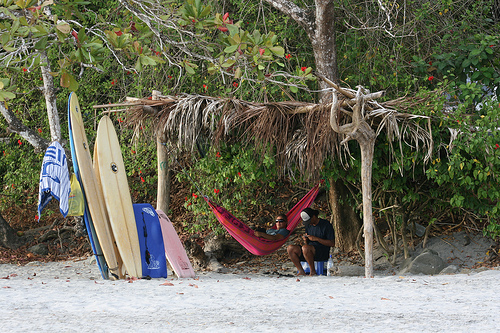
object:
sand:
[0, 252, 499, 332]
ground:
[0, 220, 498, 332]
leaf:
[386, 112, 400, 143]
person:
[287, 206, 335, 276]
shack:
[90, 72, 438, 276]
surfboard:
[92, 115, 142, 281]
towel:
[33, 141, 71, 223]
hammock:
[171, 145, 326, 256]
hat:
[300, 208, 318, 227]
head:
[300, 207, 318, 225]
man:
[254, 213, 290, 255]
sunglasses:
[275, 219, 287, 223]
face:
[275, 216, 286, 228]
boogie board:
[152, 210, 198, 279]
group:
[63, 92, 195, 283]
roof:
[102, 91, 439, 170]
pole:
[330, 86, 393, 278]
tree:
[255, 0, 370, 263]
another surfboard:
[68, 91, 121, 281]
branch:
[1, 99, 64, 150]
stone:
[408, 247, 457, 275]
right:
[339, 0, 499, 332]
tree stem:
[307, 1, 361, 261]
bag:
[67, 174, 85, 217]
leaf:
[269, 46, 285, 58]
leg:
[302, 241, 328, 272]